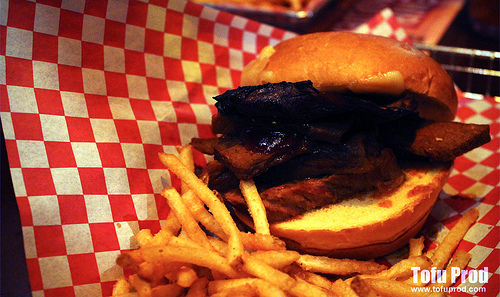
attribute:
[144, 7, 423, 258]
sandwich — small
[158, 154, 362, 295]
fries — golden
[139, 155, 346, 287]
fries — golden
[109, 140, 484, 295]
fries — brown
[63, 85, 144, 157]
paper — red, white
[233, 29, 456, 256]
bun — brown